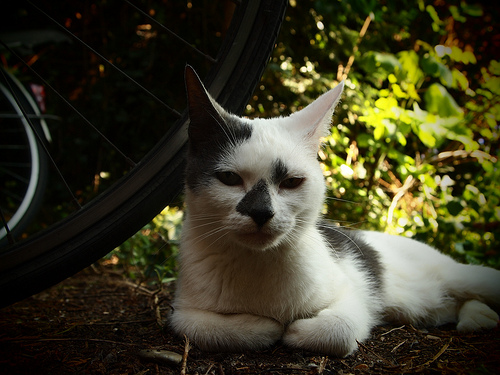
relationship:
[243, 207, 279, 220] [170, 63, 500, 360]
nose on cat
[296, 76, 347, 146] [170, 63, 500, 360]
ear on cat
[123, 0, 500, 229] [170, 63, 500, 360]
tree behind cat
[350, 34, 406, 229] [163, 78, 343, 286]
tree behind cat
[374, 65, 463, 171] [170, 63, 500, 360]
green trees behind cat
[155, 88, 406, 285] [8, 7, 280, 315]
cat lying next to wheel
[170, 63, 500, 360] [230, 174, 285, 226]
cat has patch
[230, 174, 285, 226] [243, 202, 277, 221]
patch above nose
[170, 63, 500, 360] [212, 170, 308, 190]
cat has eyes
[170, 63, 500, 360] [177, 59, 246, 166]
cat has ear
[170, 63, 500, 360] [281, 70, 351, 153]
cat has ear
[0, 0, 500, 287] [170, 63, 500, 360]
bush behind cat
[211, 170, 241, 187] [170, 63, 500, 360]
right eye of cat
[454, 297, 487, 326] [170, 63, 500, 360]
foot of cat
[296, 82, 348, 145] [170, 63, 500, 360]
ear of cat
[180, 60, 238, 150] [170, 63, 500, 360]
ear of cat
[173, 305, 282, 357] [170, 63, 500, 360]
leg of cat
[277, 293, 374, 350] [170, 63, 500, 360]
leg of cat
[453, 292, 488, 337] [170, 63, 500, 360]
leg of cat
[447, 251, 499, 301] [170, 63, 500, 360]
tail of cat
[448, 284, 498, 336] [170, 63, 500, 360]
paw of cat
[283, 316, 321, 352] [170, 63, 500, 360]
paw of cat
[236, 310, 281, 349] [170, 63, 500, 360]
paw of cat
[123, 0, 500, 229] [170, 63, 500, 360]
tree in back of cat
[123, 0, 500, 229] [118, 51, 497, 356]
tree in back of cat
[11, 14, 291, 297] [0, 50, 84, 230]
bicycle parked next to bicycle